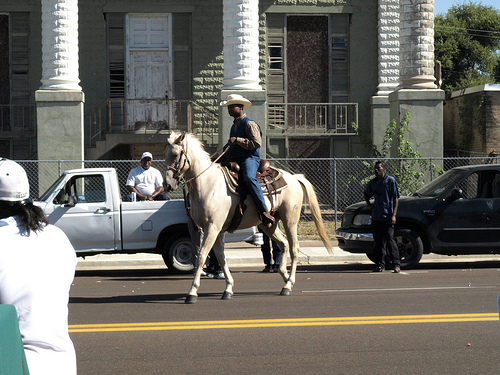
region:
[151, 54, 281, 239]
man riding on a horse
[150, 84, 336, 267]
a white horse walking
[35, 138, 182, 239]
man sitting in a white truck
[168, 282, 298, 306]
the horses hooves are black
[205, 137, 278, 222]
the saddle is brown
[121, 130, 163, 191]
man with a white shirt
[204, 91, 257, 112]
man wearing a white cowboy hat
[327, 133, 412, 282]
man standing behind the horse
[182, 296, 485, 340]
two yellow lines on the street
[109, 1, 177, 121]
a dirty white door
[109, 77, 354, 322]
person on horse in street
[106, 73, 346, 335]
male person on horse in street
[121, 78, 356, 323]
cowboy person on horse in street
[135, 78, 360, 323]
man on horse in street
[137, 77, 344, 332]
cowboy on horse in street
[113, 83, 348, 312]
person on nice horse in street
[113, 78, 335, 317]
person on beautiful horse in street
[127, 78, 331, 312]
person on healthy horse in street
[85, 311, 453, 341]
yellow line in the street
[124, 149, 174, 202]
man wearing a white shirt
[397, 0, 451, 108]
A tiled stone pillar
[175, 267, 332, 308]
Hooves on the horse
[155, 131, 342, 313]
A tan horse.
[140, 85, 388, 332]
A man riding a horse.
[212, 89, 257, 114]
A cowboy hat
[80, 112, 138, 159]
Stairs on the building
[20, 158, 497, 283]
A chained length fence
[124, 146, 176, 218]
A man sitting in the back of a pick-up truck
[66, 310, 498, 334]
Yellow lines painted on the street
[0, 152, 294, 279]
A white colored truck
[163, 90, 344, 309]
A man riding a horse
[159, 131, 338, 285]
The horse is gray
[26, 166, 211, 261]
The pickup truck is white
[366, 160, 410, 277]
The man leaning on a black SUV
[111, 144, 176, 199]
The man is sitting down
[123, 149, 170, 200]
The man is wearing a white cap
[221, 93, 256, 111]
The man is wearing a tan hat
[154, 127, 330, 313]
The horse is in the steet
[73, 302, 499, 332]
The yellow line on the street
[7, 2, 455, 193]
The house is old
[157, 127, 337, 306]
white horse walking down street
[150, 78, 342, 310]
man riding white horse down the street whiel wearing cowboy hat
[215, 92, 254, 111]
white cowboy hat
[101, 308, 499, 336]
yellow lines drawn down the center of street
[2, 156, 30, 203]
white baseball cap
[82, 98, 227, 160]
set of stairs in front of building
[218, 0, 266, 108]
white pillar in front of building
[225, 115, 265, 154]
blue denim vest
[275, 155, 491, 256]
metal fence in fornt of building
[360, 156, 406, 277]
person standing in street watching man ride horse down street